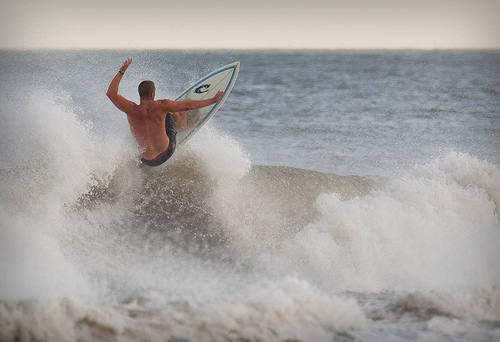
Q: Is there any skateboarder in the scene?
A: No, there are no skateboarders.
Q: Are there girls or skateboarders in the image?
A: No, there are no skateboarders or girls.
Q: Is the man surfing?
A: Yes, the man is surfing.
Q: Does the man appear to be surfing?
A: Yes, the man is surfing.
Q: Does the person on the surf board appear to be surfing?
A: Yes, the man is surfing.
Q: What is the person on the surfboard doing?
A: The man is surfing.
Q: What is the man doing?
A: The man is surfing.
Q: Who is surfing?
A: The man is surfing.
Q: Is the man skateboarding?
A: No, the man is surfing.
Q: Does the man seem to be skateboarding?
A: No, the man is surfing.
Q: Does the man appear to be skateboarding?
A: No, the man is surfing.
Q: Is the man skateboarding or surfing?
A: The man is surfing.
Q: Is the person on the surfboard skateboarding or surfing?
A: The man is surfing.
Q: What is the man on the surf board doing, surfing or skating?
A: The man is surfing.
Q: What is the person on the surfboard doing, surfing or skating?
A: The man is surfing.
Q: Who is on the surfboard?
A: The man is on the surfboard.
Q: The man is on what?
A: The man is on the surfboard.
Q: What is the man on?
A: The man is on the surfboard.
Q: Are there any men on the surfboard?
A: Yes, there is a man on the surfboard.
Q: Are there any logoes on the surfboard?
A: No, there is a man on the surfboard.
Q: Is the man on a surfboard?
A: Yes, the man is on a surfboard.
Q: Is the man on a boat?
A: No, the man is on a surfboard.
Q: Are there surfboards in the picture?
A: Yes, there is a surfboard.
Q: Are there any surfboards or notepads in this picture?
A: Yes, there is a surfboard.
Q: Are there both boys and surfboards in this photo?
A: No, there is a surfboard but no boys.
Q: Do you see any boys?
A: No, there are no boys.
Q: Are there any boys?
A: No, there are no boys.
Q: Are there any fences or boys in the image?
A: No, there are no boys or fences.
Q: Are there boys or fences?
A: No, there are no boys or fences.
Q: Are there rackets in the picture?
A: No, there are no rackets.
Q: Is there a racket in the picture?
A: No, there are no rackets.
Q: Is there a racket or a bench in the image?
A: No, there are no rackets or benches.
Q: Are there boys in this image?
A: No, there are no boys.